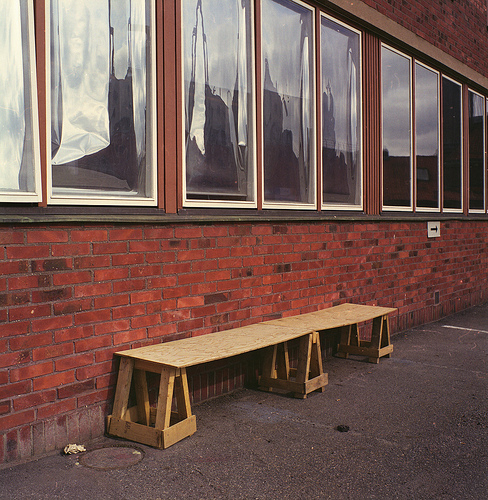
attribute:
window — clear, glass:
[380, 40, 466, 217]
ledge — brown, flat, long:
[62, 212, 416, 224]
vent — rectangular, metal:
[430, 289, 443, 307]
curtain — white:
[196, 12, 249, 155]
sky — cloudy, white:
[389, 71, 410, 133]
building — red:
[419, 156, 435, 205]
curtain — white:
[269, 36, 309, 154]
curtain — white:
[326, 65, 353, 161]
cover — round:
[71, 443, 147, 479]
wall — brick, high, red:
[59, 252, 232, 295]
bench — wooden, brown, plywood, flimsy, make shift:
[95, 282, 401, 433]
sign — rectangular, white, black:
[422, 220, 445, 242]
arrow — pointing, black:
[427, 226, 440, 234]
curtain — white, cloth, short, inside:
[56, 11, 116, 164]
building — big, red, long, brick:
[16, 10, 483, 303]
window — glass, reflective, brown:
[43, 4, 170, 215]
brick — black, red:
[31, 256, 78, 273]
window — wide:
[184, 1, 363, 212]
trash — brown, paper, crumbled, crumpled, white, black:
[56, 437, 87, 457]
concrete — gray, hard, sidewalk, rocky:
[231, 419, 478, 498]